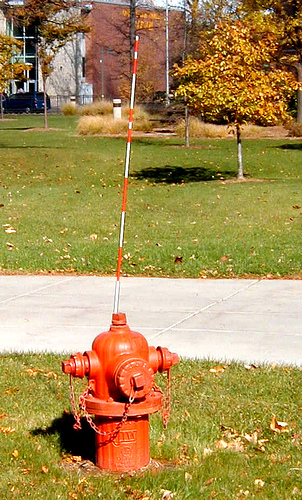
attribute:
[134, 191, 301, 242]
grassy area — green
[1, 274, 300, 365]
sidewalk — side, cement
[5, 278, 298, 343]
sidewalk — cement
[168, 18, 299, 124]
colorful foliage — yellow, orange, red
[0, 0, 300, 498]
outdoors — scenic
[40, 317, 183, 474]
hydrant — fire 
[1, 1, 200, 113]
building — brown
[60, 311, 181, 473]
hydrant — red fire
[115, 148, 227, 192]
leaves — brown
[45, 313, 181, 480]
hydrant — red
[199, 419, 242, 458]
leaves — yellow and red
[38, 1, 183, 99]
walls — white